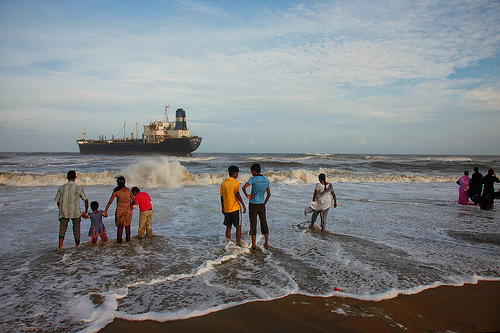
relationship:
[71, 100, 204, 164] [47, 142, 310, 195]
tanker on surf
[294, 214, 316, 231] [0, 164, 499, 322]
net in surf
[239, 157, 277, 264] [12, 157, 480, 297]
boy standing in water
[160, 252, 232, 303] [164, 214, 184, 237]
water has part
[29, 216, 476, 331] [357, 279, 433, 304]
shore has edge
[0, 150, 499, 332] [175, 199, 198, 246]
water has part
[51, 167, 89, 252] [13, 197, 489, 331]
person in beach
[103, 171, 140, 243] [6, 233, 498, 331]
person in beach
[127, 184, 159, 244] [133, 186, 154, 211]
person wears red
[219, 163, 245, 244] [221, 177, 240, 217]
person wears shirt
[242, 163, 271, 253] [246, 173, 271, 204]
person wears blue shirt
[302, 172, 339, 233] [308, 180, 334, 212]
woman wears shirt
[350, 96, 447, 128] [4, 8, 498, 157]
cloud covers sky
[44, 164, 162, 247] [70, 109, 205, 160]
family watch tanker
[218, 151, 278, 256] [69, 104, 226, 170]
friends watch tanker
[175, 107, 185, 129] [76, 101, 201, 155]
smokestack on ship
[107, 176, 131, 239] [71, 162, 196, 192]
woman in water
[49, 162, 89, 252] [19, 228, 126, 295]
man in water